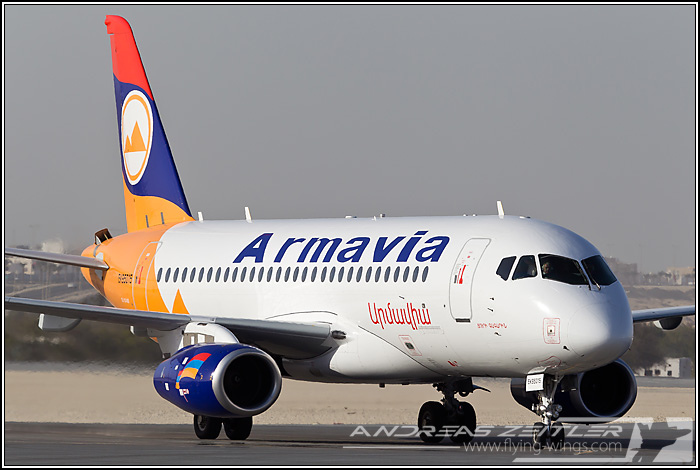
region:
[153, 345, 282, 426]
Engine on a plane.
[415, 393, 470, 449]
Black tire on a plane.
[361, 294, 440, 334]
Red writing on a plane.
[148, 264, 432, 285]
Windows on a plane.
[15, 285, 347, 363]
Wing on a plane.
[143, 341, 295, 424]
Blue, orange and red engine on a plane.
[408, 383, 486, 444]
Landing gear on a plane.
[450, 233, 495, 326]
Door on a plane.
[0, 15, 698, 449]
the airplane is white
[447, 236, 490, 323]
the white door on the airplane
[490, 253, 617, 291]
the windshield of the cockpit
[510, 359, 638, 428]
the turbine engine on the bottom of the plane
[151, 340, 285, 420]
the blue turbine on the wing of the airplane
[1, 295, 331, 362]
the wing of the airplane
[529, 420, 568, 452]
the front wheels of the landing gear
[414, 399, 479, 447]
the wheels under the plane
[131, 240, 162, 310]
the yellow door of the plane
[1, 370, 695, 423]
the dirt field behind the plane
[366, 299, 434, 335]
Red letters on the plane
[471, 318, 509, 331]
Red letters on the plane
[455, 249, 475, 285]
Red letters on the plane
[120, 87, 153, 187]
White and orange logo on the plane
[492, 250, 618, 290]
Front windows of the plane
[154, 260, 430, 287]
Side windows of the plane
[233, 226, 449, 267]
Blue letters on the plane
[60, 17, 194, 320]
Red, blue, white, and orange tail of the plane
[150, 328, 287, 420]
Blue and silver engine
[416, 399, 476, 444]
Wheels of the plane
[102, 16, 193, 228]
Red,blue,and gold tail of plane.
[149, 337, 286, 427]
Right engine of plane.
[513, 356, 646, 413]
Left engine of plane.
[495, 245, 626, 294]
Cockpit windows of the airplane.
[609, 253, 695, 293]
Buildings are in the distance.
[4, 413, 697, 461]
Runway is black asphalt.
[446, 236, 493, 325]
White door of plane at front.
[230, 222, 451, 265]
Letters written in blue.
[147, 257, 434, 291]
Row of airplane windows.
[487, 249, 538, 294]
window on a plane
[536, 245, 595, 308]
window on a plane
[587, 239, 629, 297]
window on a plane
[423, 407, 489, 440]
tires on a plane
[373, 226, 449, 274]
letters on a plane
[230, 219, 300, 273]
letters on a plane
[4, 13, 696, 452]
airplane on the runway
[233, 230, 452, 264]
the word "Armavia" on the side of the plane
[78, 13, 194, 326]
red, blue, and yellow tail of the plane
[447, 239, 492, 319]
white door on the side of the plane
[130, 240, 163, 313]
yellow door on the side of the plane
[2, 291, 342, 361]
right wing of the plane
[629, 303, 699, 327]
left wing of the plane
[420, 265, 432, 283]
an oval window on the side of the plane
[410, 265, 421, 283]
an oval window on the side of the plane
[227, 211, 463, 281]
the letters are blue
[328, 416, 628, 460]
the letters are white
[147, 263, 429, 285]
a row of windows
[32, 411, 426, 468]
a shadow on the ground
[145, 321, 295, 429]
blue paint on plane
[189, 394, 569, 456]
the wheels of plane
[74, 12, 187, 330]
the tail of plane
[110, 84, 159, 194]
a white circle on plane